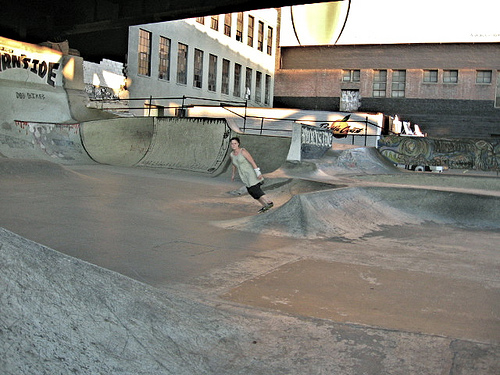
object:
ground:
[0, 162, 500, 373]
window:
[137, 28, 153, 78]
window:
[157, 34, 172, 83]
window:
[176, 40, 189, 86]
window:
[192, 47, 204, 89]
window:
[207, 53, 218, 92]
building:
[127, 7, 279, 117]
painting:
[0, 44, 62, 101]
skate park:
[1, 34, 498, 372]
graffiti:
[377, 135, 500, 173]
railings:
[238, 115, 401, 147]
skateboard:
[258, 202, 275, 214]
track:
[0, 35, 499, 373]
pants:
[245, 182, 266, 200]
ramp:
[300, 187, 416, 242]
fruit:
[329, 119, 349, 139]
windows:
[220, 58, 230, 96]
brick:
[298, 86, 305, 89]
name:
[0, 52, 61, 89]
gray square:
[0, 169, 499, 343]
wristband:
[249, 164, 262, 181]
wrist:
[254, 167, 262, 176]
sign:
[15, 91, 46, 101]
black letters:
[46, 62, 59, 88]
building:
[272, 0, 500, 172]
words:
[301, 127, 333, 148]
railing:
[87, 94, 248, 116]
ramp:
[78, 116, 295, 182]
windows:
[371, 68, 387, 98]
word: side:
[21, 54, 61, 90]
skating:
[251, 192, 281, 211]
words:
[0, 53, 60, 89]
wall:
[0, 37, 131, 166]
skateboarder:
[229, 137, 274, 214]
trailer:
[184, 105, 443, 174]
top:
[229, 147, 265, 188]